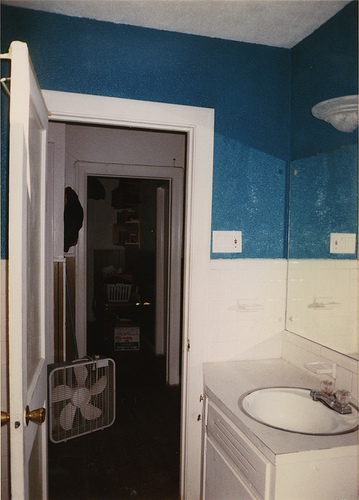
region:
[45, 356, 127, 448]
box fan on the floor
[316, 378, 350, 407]
two clear knobs on the faucet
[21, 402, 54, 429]
gold doorknob on the door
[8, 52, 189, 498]
the door is open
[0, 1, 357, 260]
blue paint on the wall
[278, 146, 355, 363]
mirror on the wall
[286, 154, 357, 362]
reflection in the mirror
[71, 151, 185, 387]
thick white door frame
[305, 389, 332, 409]
silver faucet hanging over the sink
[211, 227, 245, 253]
light switches on the wall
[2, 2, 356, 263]
Blue painted bathroom wall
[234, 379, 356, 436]
White bathroom sink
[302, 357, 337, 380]
White soap holder mounted on wall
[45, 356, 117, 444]
Stand up box fan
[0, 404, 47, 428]
Old copper bathroom door handles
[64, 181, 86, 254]
Garment hanging on wall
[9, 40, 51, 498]
White bathroom door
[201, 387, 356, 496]
Old white bathroom cabinets under sink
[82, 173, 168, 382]
Open doorway to a dark room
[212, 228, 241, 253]
Electrical outlet on a bathroom wall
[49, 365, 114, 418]
White box fan on floor.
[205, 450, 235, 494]
White cupboard under sink.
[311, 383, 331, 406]
Silver faucet on sink.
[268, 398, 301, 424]
Inside of sink is white.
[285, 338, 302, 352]
White tiles on wall above sink.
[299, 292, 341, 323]
Large mirror above sink.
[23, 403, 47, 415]
Gold door handle on door.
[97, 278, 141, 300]
White laundry basket in room.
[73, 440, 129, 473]
Floor is dark in color.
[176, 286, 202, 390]
Door frame is white in room.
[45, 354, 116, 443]
White box fan.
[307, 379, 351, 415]
Faucet with a handle for hot and cold water.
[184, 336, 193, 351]
Strike plate for bathroom door.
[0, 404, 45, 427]
Door knob on bathroom door.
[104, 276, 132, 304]
White laundry basket.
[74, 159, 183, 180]
Top piece of casing on a door.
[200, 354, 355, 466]
White bathroom counter top.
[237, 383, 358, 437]
White sink with a metal ring around it.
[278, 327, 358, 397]
White tile back splash.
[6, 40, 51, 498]
White bathroom door.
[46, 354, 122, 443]
Square white fan on the floor.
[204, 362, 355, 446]
White bathroom sink.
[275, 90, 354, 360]
Mirror above bathroom sink.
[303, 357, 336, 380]
White soap dish on the wall.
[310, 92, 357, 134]
Reflection of the light fixture in the mirror.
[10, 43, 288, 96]
Blue paint on the wall.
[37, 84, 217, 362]
White trim around the door.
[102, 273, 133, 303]
White basket full of clothes.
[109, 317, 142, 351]
A box under the table.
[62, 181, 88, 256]
A jacket hanging on the wall.